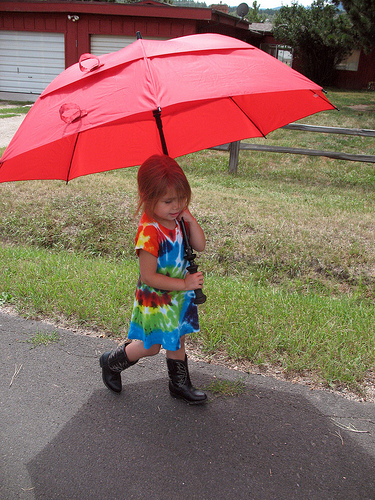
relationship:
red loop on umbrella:
[55, 99, 92, 124] [3, 22, 346, 196]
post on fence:
[241, 143, 372, 164] [221, 120, 373, 177]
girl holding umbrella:
[87, 146, 220, 410] [3, 22, 346, 196]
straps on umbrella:
[55, 51, 106, 125] [3, 22, 346, 196]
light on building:
[64, 12, 81, 23] [1, 0, 374, 107]